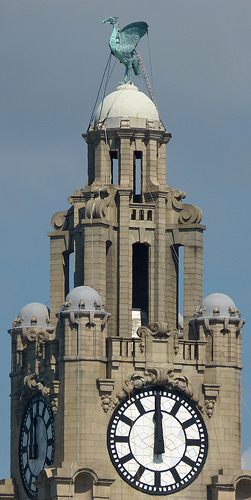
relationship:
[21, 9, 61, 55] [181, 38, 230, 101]
clouds in sky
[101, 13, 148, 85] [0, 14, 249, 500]
animal on building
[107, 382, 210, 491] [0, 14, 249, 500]
clock in building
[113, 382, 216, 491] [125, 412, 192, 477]
clock with face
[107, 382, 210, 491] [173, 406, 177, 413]
clock with marks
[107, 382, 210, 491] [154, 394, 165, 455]
clock has hands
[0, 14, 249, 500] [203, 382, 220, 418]
building has shelf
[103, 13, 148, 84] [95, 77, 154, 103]
animal on top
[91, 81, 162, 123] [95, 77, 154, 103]
dome has top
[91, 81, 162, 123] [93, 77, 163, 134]
dome has top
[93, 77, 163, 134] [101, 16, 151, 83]
top has sculpture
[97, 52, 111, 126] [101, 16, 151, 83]
cable securing sculpture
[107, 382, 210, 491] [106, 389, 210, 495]
clock has face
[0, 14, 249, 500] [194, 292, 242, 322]
building has dome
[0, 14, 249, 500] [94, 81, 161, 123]
building has dome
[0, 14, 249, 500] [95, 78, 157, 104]
building has top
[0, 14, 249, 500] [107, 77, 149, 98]
building has top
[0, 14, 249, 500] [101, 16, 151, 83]
building has sculpture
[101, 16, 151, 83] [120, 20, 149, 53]
sculpture has wing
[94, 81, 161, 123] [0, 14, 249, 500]
dome atop building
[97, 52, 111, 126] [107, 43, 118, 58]
cable attached to piece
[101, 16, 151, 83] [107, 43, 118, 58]
sculpture has piece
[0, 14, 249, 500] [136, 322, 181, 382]
building has details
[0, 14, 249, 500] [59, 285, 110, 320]
building has detail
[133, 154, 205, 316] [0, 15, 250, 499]
cable attached to tower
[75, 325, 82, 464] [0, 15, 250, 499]
stain dripping down tower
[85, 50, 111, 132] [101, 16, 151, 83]
cable attached to sculpture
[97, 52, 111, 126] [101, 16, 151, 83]
cable attached to sculpture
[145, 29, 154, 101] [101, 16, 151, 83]
cable attached to sculpture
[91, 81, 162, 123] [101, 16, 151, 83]
dome under sculpture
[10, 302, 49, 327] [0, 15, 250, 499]
dome on tower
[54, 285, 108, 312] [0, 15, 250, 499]
dome on tower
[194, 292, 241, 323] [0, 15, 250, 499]
dome on tower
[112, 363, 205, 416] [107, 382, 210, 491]
design above clock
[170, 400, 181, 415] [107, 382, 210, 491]
line on clock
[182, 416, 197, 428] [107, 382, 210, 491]
line on clock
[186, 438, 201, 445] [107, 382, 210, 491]
line on clock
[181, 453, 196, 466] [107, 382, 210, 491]
line on clock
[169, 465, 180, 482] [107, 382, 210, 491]
line on clock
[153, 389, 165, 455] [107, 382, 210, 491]
hands on clock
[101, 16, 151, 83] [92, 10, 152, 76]
sculpture of bird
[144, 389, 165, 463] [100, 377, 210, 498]
hands on clock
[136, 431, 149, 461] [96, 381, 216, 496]
cracks on clock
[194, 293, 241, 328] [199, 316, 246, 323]
dome on roof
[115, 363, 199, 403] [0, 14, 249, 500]
design on building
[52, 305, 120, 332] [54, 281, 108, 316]
designs on dome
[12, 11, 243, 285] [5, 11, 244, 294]
sky with clouds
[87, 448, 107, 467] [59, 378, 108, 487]
stone in wall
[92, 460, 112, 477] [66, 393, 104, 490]
stone in wall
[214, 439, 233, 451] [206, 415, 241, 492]
stone in wall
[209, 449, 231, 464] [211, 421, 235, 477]
stone in wall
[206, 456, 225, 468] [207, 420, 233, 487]
stone in wall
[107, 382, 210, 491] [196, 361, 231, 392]
clock on building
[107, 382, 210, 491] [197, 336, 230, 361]
clock on building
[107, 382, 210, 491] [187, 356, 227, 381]
clock on building